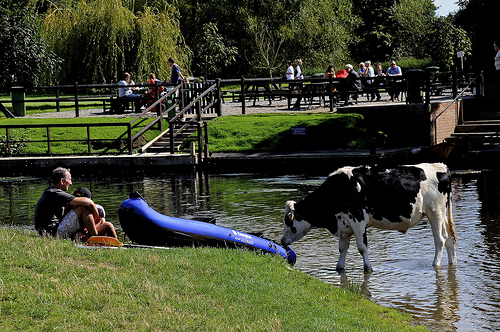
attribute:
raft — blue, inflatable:
[113, 186, 306, 268]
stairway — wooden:
[116, 109, 201, 150]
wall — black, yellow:
[414, 106, 474, 184]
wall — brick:
[332, 85, 441, 159]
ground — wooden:
[393, 212, 427, 243]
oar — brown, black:
[85, 232, 171, 251]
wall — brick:
[433, 104, 451, 136]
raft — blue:
[100, 175, 276, 253]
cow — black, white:
[275, 156, 460, 277]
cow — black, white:
[275, 161, 467, 272]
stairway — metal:
[428, 73, 498, 155]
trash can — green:
[6, 83, 30, 118]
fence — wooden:
[3, 122, 133, 157]